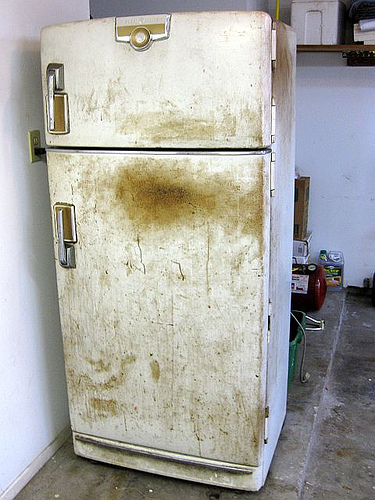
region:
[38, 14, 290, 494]
old refrigerator in the room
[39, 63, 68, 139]
freezer handle of the refrigerator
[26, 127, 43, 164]
outlet with something plugged in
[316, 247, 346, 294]
bottle of a chemical against the wall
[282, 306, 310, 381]
green basket with obects in it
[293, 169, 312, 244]
brown box on top of smaller white boxes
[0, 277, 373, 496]
dirty concrete ground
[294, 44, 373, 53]
brown wooded shelf up high on the wall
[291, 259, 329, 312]
red metal tank in the background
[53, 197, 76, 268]
refrigerator handle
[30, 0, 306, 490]
the refrigerator is old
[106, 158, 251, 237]
big brown spot on refrigerator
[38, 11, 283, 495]
brown spots on refrigerator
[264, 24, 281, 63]
hinge on door of refrigerator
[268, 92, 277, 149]
hinge on door of refrigerator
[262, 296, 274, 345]
hinge on door of refrigerator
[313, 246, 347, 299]
a bottle on the floor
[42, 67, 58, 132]
handle of refrigerator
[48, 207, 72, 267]
handle of refrigerator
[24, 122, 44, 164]
a switch behind the refrigerator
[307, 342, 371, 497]
The ground is made of concrete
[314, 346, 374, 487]
The color of the ground is gray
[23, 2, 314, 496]
The refrigerator is the color white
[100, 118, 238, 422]
The refrigerator is old and dirty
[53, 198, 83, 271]
The handle of the refrigerator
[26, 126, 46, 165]
The plug on the wall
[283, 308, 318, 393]
A green basket on the ground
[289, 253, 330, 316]
A red tank on the ground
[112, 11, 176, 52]
The logo on the refrigerator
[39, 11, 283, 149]
The top of the refrigerator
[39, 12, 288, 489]
a dirty fridge is on concrete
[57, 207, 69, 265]
handle on a fridge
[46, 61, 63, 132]
handle on a fridge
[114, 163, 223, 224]
dirt spot on a fridge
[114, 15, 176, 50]
logo on a fridge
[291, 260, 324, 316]
a red air compressor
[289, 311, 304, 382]
end of a green bin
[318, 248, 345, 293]
a plastic bottle that is full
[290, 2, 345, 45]
a cooler on a shelf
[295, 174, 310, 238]
a box of cardboard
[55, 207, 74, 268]
Metal latch door handle on refrigerator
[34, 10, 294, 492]
Old unused stained refrigerator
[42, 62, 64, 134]
Metal latch handle on freezer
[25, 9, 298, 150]
Freezer section of old refrigerator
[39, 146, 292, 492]
Lower refrigerator part of appliance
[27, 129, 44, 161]
Electric power outlet on wall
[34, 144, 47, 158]
Black power cord in outlet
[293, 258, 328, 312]
Part of air compressor pump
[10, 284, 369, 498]
Concrete floor in room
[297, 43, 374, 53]
Wooden storage shelf in room